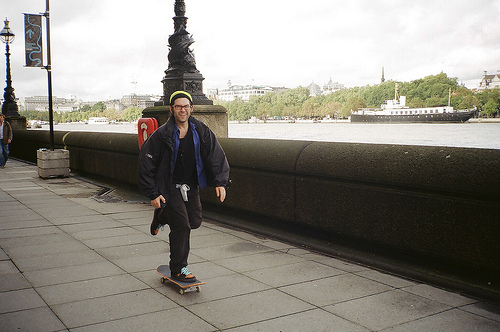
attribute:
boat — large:
[351, 81, 480, 124]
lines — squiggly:
[25, 14, 45, 67]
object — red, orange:
[137, 118, 159, 150]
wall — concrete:
[10, 132, 499, 299]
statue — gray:
[160, 0, 206, 102]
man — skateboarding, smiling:
[137, 90, 231, 295]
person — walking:
[0, 111, 13, 168]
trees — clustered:
[299, 70, 500, 117]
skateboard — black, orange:
[156, 264, 206, 296]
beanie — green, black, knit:
[168, 89, 194, 103]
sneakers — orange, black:
[150, 206, 197, 283]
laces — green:
[177, 266, 193, 276]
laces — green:
[154, 221, 166, 231]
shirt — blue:
[169, 124, 208, 191]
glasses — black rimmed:
[174, 104, 191, 114]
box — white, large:
[37, 148, 70, 179]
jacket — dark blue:
[137, 117, 230, 198]